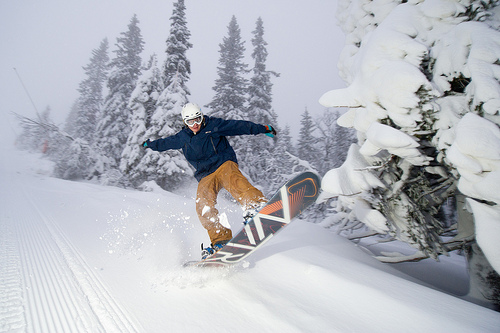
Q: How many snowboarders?
A: One.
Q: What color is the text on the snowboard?
A: White.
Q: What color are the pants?
A: Yellow.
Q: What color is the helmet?
A: White.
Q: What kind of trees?
A: Pine.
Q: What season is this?
A: Winter.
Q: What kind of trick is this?
A: Jump.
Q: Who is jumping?
A: Snowboarder.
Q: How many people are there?
A: 1.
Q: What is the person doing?
A: Snowboarding.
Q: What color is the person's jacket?
A: Blue.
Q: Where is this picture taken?
A: On a mountain.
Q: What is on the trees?
A: Snow.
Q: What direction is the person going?
A: Downhill.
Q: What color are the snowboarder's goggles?
A: White.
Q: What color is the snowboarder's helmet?
A: White.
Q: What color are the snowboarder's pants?
A: Khaki.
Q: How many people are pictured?
A: One.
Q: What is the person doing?
A: Snowboarding.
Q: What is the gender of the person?
A: Male.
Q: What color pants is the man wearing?
A: Brown.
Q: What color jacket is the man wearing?
A: Blue.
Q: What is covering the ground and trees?
A: Snow.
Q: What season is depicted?
A: Winter.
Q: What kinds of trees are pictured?
A: Evergreens.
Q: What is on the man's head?
A: Helmet.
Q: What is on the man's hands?
A: Gloves.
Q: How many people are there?
A: One.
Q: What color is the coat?
A: Blue.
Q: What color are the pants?
A: Brown.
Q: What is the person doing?
A: Snowboarding.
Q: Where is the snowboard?
A: Under the person.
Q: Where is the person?
A: On the snowboard.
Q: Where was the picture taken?
A: On a snowy slope.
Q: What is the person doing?
A: Snowboarding.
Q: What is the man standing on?
A: A snowboard.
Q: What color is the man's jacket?
A: Blue.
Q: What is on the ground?
A: Snow.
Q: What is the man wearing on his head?
A: Helmet.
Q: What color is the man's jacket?
A: Brown.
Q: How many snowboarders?
A: One.